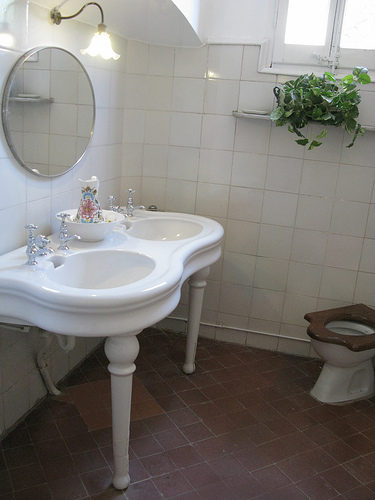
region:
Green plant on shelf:
[264, 63, 373, 154]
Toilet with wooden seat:
[296, 273, 373, 428]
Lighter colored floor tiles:
[53, 364, 168, 454]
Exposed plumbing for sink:
[32, 327, 83, 402]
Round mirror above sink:
[4, 34, 103, 182]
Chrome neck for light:
[50, 0, 119, 33]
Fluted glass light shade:
[74, 23, 124, 64]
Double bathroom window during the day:
[265, 3, 373, 80]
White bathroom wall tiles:
[226, 157, 342, 270]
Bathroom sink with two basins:
[0, 188, 244, 333]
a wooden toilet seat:
[304, 301, 374, 352]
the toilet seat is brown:
[303, 302, 374, 351]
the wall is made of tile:
[0, 1, 373, 437]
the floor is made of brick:
[0, 325, 372, 498]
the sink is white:
[1, 205, 224, 305]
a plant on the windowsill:
[270, 64, 372, 149]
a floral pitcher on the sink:
[54, 175, 125, 242]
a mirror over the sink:
[2, 45, 96, 177]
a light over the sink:
[50, 1, 120, 59]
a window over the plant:
[256, 1, 373, 84]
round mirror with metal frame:
[2, 37, 103, 185]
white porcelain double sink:
[3, 195, 219, 331]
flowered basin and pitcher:
[56, 172, 124, 243]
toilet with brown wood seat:
[286, 279, 368, 411]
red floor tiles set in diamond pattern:
[189, 380, 306, 479]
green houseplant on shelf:
[265, 63, 369, 153]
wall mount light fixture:
[49, 2, 129, 68]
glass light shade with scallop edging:
[77, 22, 128, 70]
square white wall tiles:
[148, 50, 226, 173]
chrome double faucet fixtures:
[16, 209, 81, 264]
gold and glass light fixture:
[45, 5, 125, 67]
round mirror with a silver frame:
[4, 46, 98, 179]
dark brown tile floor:
[180, 394, 371, 497]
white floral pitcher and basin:
[58, 165, 127, 245]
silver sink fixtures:
[19, 210, 90, 271]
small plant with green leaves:
[262, 70, 373, 145]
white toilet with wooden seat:
[298, 296, 374, 410]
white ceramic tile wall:
[230, 122, 369, 287]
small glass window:
[269, 1, 374, 78]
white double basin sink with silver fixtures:
[1, 178, 228, 355]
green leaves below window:
[265, 60, 370, 129]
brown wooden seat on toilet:
[301, 291, 373, 378]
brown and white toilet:
[299, 284, 370, 402]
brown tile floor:
[147, 354, 325, 490]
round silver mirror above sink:
[6, 41, 117, 207]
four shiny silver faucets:
[21, 183, 146, 265]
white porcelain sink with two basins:
[8, 184, 233, 428]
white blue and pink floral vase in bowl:
[71, 177, 118, 262]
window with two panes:
[261, 6, 356, 67]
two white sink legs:
[69, 242, 234, 492]